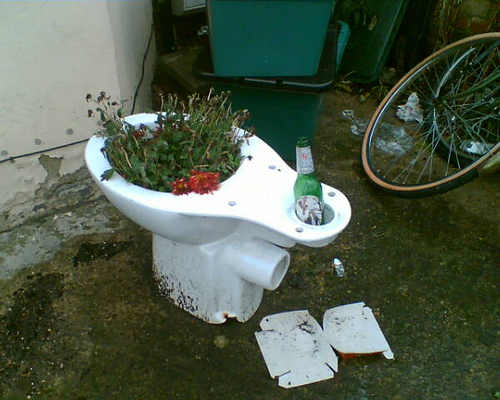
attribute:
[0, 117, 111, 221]
paint — peeling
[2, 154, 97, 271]
paint — peeled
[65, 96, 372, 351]
toilet — old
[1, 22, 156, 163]
wires — black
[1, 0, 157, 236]
wall — beige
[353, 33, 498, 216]
wheel — large, bike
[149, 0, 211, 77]
space — dark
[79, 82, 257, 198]
plant — flowering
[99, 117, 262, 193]
bowl — toilet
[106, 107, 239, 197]
bowl — toilet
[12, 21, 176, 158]
wall — angled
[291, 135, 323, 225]
beer bottle — green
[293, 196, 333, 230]
toilet hole — smaller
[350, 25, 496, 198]
bike tire — large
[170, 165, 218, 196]
flowers — red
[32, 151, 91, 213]
paint — peeling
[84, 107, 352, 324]
toilet — filthy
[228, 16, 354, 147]
bin — green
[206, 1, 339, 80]
bin — green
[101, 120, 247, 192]
bowl — toilet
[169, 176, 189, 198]
flower — dried up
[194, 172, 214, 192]
flower — dried up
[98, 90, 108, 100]
flower — dried up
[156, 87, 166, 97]
flower — dried up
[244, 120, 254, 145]
flower — dried up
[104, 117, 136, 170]
stem — green, leafy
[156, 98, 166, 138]
stem — green, leafy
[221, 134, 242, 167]
stem — green, leafy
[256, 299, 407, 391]
container — flattened, paper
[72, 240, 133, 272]
shape — black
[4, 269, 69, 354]
shape — black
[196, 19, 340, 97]
lid — black